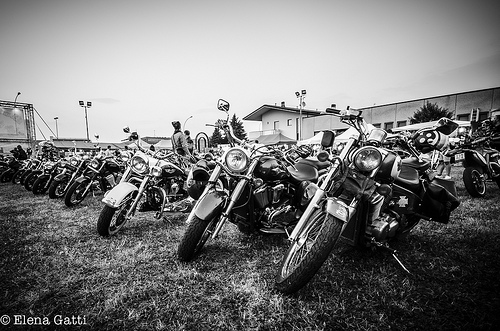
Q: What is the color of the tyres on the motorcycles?
A: Black.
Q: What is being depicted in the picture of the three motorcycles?
A: Wheels.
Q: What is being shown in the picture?
A: Motorcycles.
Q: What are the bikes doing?
A: Waiting.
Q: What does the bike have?
A: Tires.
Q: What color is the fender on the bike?
A: White.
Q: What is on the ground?
A: Grass.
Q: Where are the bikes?
A: On grass.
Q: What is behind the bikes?
A: Buildings.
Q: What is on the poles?
A: Lights.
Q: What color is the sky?
A: White.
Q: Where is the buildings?
A: Behind the bike.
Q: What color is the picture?
A: Black and white.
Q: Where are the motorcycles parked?
A: On the grass.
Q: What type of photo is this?
A: Black and white.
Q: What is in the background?
A: A building.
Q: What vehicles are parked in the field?
A: Motorcycles.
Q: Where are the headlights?
A: On the front of the motorcycles.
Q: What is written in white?
A: Elena Gatti.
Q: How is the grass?
A: Short and scruffy.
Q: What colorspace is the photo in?
A: Black and white.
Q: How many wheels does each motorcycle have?
A: Two.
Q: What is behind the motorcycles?
A: A building.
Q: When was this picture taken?
A: Daytime.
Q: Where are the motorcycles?
A: A field.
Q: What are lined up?
A: Motorcycles.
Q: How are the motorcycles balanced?
A: Kickstands.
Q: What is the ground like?
A: Grassy.